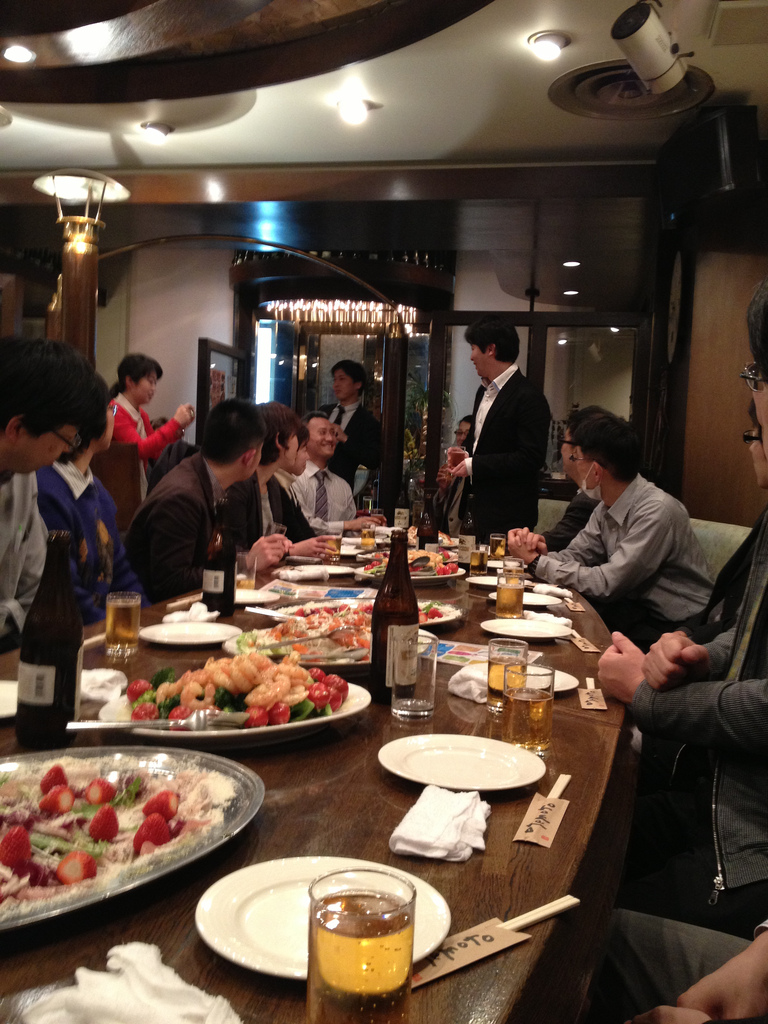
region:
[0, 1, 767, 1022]
A modern hotel establishment.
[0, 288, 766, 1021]
A group of people enjoying their meals.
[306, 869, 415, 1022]
A glass of white wine.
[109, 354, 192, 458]
The young woman in red.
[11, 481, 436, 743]
Five wine bottles on the table.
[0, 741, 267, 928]
A tray full of strawberry.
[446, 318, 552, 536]
The man with a black suit.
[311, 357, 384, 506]
The man at the door.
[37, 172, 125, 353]
A suspended ceiling lighting.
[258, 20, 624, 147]
white lights on ceilng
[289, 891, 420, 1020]
clear glass with liquid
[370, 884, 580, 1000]
chopsticks in paper holder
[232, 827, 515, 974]
white and round plate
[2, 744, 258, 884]
large and silver tray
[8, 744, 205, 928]
red radishes in tray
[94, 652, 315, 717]
pink shrimp in tray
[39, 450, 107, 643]
woman has blue shirt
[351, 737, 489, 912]
white towel on table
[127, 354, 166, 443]
red and white shirt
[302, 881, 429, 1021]
glass with amber liquid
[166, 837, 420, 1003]
white and round plate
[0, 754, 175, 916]
red radishes on tray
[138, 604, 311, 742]
pink shrimp on tray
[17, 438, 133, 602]
woman has blue shirt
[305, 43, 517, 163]
white lights on ceiling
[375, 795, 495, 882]
white napkin on table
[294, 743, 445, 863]
table is dark brown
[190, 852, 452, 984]
White plate on the table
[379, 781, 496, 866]
White napkin on the table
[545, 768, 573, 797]
Chopsticks inside of a small paper bag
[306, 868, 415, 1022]
Glass of beer next to the white plate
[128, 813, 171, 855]
Strawberry on the silver tray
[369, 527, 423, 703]
Large bottle of beer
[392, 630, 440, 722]
Empty glass next to the beer bottle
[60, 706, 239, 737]
Silver fork on the white plate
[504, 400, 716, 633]
Man wearing a gray button down shirt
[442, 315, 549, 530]
Man wearing a black jacket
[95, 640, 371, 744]
shrimp on a white plate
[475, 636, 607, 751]
drinks in a glass on wooden table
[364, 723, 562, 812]
empty white plate on a table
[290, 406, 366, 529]
smiling man in white shirt and tie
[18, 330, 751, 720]
several people sitting around a table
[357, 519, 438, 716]
bottle of wine sitting on a table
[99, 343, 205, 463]
woman with a camera taking pictures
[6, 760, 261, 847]
strawberries on a silver platter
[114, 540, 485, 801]
several plates of food on a table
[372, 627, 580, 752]
empty glass next to two full glasses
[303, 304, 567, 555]
two men standing up with ties on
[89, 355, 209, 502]
a woman wearing a red jacket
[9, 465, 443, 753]
four bottles of wine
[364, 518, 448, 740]
an empty glass beside a wine bottle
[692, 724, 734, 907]
an open zipper on a jacket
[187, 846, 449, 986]
the empty plate closest to the camera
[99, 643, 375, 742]
a plate with a pile of shrimp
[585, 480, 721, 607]
man wearing a gray shirt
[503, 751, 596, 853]
chopsticks on the table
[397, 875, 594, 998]
chopsticks on the table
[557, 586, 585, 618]
chopsticks on the table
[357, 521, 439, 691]
Beer bottle on the table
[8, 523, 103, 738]
Beer bottle on the table